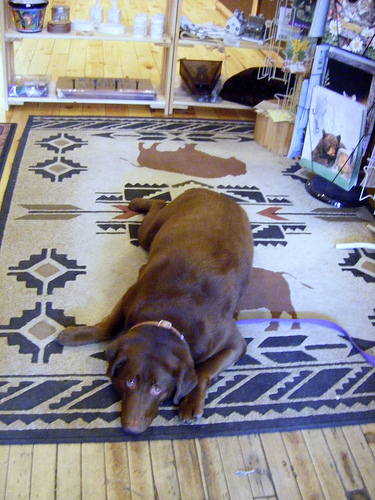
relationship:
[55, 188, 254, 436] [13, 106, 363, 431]
dog laying on carpet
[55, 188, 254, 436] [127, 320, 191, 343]
dog wearing collar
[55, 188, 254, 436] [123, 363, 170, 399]
dog has eyes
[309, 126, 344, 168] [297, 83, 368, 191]
bear on picture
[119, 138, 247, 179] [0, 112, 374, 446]
buffalo on carpet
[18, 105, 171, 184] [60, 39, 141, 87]
carpet on floor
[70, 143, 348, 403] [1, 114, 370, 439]
dog lounging on rug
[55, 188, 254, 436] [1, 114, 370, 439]
dog laying on rug